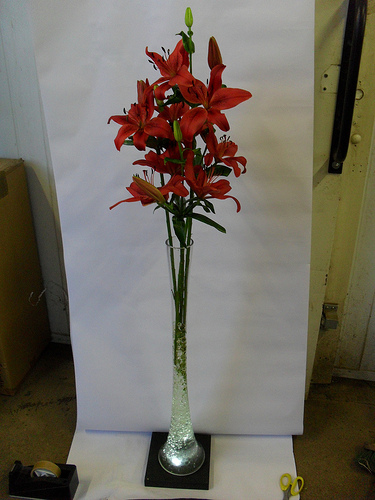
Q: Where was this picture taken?
A: In a house.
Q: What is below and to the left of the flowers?
A: A tape dispenser.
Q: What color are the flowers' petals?
A: Red.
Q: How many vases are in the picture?
A: One.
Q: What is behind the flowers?
A: White paper.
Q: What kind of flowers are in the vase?
A: Tiger lilies.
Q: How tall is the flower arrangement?
A: About 3-4 feet.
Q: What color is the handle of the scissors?
A: Yellow.